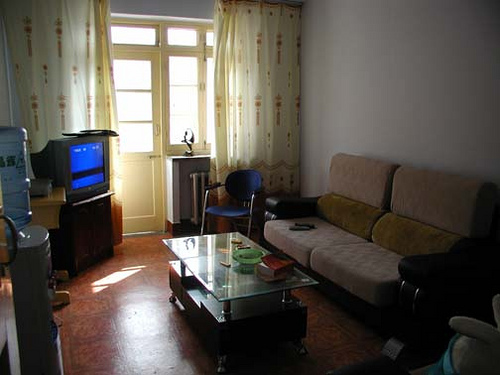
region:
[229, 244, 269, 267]
Green bowl on coffee table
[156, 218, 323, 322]
Glass top on coffee table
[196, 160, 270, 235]
Blue chair next to couch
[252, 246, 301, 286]
Big book on a coffee table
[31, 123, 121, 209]
Television on a small table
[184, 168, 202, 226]
Metal radiator on wall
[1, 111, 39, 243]
Blue water bottle on a water cooler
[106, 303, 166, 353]
Red tile on a floor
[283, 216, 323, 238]
remote controls on a couch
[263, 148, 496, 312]
couch in a room against a wall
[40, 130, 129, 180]
A black analog television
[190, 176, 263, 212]
A small blue chair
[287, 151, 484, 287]
A grey and green coach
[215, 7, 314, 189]
A long door curtain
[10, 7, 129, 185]
A long door curtain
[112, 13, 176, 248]
A beige wooden ang glass door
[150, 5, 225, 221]
A beige wooden ang glass door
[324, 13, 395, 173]
A white paint wall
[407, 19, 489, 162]
A white paint wall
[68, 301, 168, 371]
A brown smooth floor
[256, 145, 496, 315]
beige and lime green love seat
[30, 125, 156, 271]
television on a television set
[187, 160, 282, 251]
silver and grey chair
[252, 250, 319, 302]
book on a table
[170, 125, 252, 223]
trophy on a fireplace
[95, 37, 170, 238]
cream color door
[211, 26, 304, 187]
cream color curtains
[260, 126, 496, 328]
remote controls on the couch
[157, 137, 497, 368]
table near a couch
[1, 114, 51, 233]
big blue water jug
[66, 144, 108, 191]
blue color on front of television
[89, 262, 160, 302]
sunlight reflecting on the floor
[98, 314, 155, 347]
shiny wood flooring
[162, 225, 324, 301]
large glass table top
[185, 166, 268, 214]
blue chair with silver arms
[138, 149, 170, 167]
bracket on yellow door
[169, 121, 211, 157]
small figurine of table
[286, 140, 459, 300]
pink and green color sofa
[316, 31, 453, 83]
bare gray walls behind sofa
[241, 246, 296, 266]
thick red book on table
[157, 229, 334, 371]
glass topped coffee table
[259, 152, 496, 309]
beige coloured couch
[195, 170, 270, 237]
blue plastic and metal chair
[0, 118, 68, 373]
office water dispenser machine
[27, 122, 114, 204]
old television with a blue screen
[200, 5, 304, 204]
long light yellow curtain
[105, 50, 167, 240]
light yellow painted wooden door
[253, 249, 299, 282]
large red coloured book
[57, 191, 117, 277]
short brown wooden television stand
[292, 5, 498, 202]
white painted wall